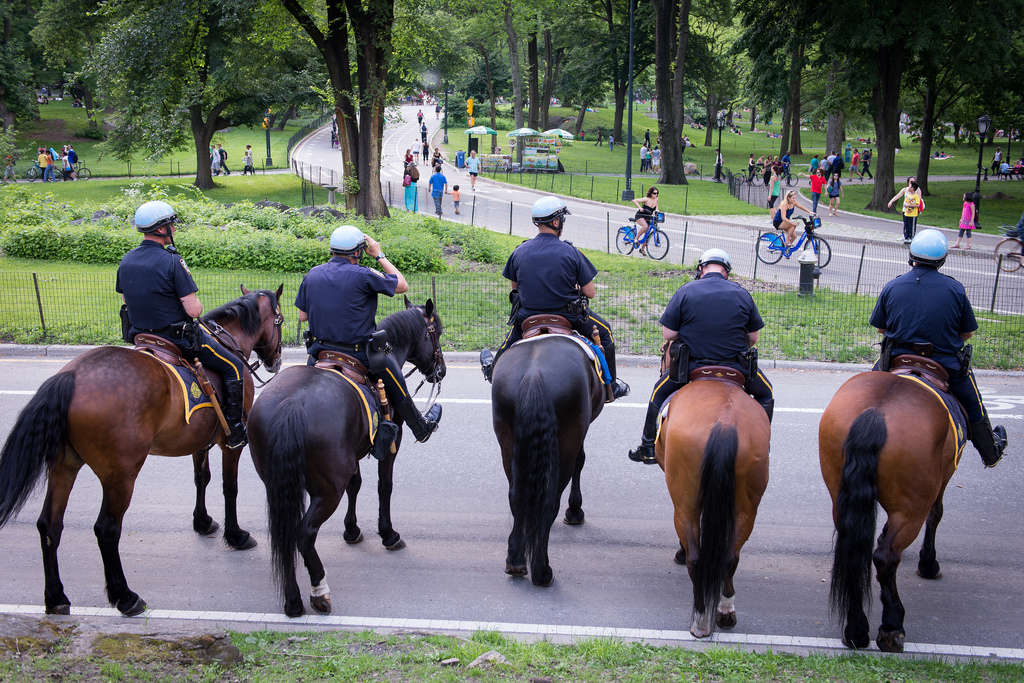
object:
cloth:
[140, 350, 223, 424]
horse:
[0, 284, 287, 618]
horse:
[247, 293, 447, 618]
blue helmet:
[909, 229, 948, 261]